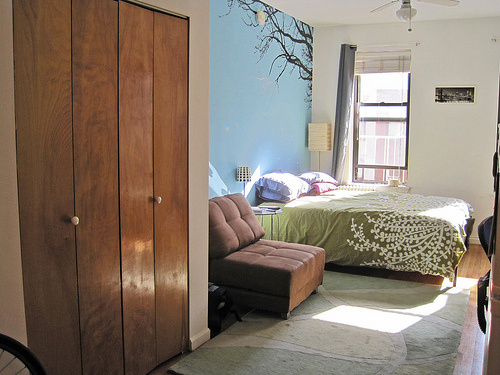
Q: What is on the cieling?
A: Fan.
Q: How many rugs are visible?
A: One.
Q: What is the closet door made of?
A: Wood.